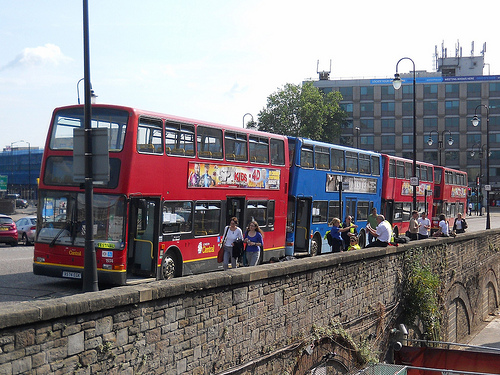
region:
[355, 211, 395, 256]
person sitting on the wall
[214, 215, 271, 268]
two women walking on the side of the bus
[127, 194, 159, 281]
door of the bus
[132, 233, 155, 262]
railing going up the stairs to the bus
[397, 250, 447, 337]
bush on the side of the wall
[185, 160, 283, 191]
banner on the side of the bus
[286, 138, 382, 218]
car of the bus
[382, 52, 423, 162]
streetlight hanging down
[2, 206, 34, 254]
cars parked in the parking lot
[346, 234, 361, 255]
woman with a yellow shirt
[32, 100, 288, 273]
A red double-deckered tour bus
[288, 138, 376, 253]
A blue section of this double-deckered bus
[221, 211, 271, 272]
Two women walking together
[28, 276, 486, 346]
A historical stone bridge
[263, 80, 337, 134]
A tall green tree behind the bus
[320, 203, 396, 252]
A group of people are together.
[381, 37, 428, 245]
A tall lamp on this bridge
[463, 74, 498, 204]
A section of this seven story building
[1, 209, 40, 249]
Two sedan cars are parked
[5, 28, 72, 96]
A single cloud floating in the sky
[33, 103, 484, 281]
four city buses in a row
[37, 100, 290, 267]
a red city bus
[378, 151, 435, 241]
a red city bus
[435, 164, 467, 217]
a red city bus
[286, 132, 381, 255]
a blue city bus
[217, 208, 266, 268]
two women walking along a street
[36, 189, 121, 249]
the windshield of a bus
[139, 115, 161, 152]
the window of a bus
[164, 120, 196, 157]
the window of a bus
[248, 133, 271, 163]
the window of a bus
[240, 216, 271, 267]
Woman wearing a purple shirt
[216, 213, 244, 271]
Woman wearing a white sweater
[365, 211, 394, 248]
Man sitting on wall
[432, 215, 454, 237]
Woman sitting on wall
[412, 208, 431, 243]
Man wearing a white shirt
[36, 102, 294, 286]
Bus parked near curb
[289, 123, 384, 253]
Bus parked near curb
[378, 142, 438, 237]
Bus parked near curb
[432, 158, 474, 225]
Bus parked near curb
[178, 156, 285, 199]
Billboard on side of bus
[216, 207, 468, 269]
the people next to the buses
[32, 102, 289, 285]
the red double decker bus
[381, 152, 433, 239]
the red double decker bus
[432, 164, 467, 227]
the red double decker bus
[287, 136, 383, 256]
the blue double decker bus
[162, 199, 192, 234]
the window on the side of the bus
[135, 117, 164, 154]
the window on the side of the bus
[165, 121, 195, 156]
the window on the side of the bus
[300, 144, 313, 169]
the window on the side of the bus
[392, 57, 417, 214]
the street light next to the bus